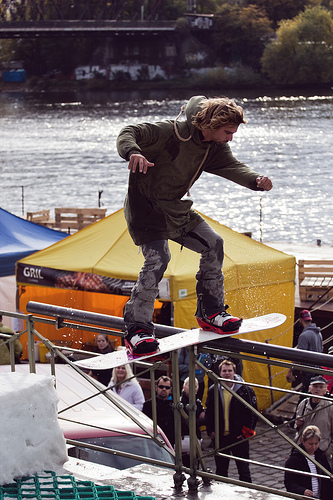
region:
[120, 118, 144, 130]
This is a man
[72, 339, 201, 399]
This is a snowboard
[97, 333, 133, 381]
the board is white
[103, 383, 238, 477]
this is a crowd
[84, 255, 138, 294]
These are dark pants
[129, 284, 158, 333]
The pants are wet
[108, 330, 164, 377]
This is a shoe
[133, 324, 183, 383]
the shoe is white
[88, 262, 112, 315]
this is a tent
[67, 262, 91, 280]
the tent is yellow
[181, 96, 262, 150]
man has blond hair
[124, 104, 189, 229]
man has green hoodie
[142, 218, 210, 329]
man has grey pants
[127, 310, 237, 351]
red and white shoes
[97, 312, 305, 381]
man is on white board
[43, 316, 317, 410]
board is on grey rail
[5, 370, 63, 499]
white block of snow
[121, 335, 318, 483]
people are watching man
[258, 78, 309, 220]
sparkling water behind man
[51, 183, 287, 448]
yellow tent behind people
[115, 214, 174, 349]
leg of a person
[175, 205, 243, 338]
leg of a person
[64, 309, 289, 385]
white snowboard on a rail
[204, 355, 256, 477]
person watching a snowboarder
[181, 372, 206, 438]
person watching a snowboarder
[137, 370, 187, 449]
person watching a snowboarder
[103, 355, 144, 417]
person watching a snowboarder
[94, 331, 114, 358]
person watching a snowboarder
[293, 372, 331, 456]
person watching a snowboarder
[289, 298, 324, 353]
person below a snowboarder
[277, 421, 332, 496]
woman in black coat reading a text message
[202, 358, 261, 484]
man in yellow shirt watching snowboarder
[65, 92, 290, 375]
man in green jacket snowboarding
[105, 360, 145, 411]
blonde haired woman in white coat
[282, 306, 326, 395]
man in red hat putting venue together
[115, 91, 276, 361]
man in red and black snow boots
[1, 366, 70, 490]
block of snow in lower right corner of picture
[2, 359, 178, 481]
red vehicle in front of the crowd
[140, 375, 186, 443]
man with shades standing in the crowd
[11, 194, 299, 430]
yellow tent used for grill at venue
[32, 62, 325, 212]
a body of water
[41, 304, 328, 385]
a white snowboard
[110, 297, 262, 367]
white and red snowboard boots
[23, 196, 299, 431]
a yellow tent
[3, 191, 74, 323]
a blue and white tent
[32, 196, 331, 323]
a wooden deck next to water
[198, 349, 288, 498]
a man wearing a black coat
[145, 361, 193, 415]
a man wearing sunglasses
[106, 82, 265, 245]
a man wearing a green jacket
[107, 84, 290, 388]
a man snowboarding